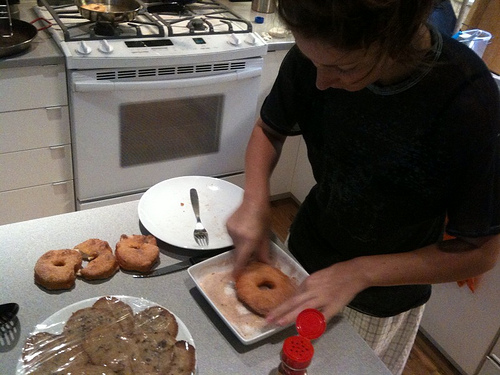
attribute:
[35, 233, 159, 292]
donuts — brown, coated, orange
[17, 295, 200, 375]
plate — white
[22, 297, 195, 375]
cookies — chocolate chip, brown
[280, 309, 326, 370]
shaker top — red, plastic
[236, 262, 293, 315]
donut — brown, being covered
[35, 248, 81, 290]
donut — brown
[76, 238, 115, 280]
donut — brown, half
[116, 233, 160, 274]
donut — brown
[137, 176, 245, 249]
plate — white, empty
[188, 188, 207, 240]
fork — metallic, grey, silver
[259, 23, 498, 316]
shirt — black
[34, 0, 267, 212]
stove — white, grey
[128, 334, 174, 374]
cookie — brown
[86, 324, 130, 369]
cookie — brown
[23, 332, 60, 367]
cookie — brown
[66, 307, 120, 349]
cookie — brown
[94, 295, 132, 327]
cookie — brown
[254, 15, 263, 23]
bottle cap — blue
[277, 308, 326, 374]
seasoning — red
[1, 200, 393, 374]
counter — grey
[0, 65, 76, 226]
cabinets — white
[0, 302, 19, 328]
spatula — black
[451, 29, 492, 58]
container — blue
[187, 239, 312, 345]
dish — square